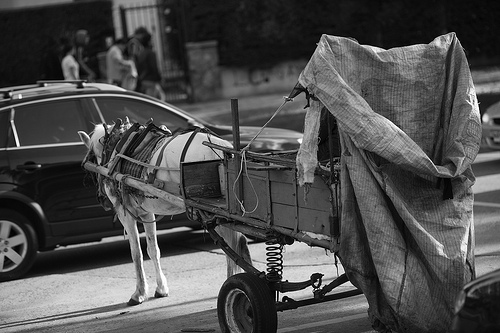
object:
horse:
[75, 121, 235, 306]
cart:
[84, 80, 499, 333]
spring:
[261, 223, 282, 282]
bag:
[290, 33, 479, 331]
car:
[0, 77, 306, 280]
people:
[60, 44, 81, 80]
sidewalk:
[202, 79, 499, 128]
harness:
[104, 130, 178, 181]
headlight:
[481, 113, 491, 123]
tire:
[215, 271, 279, 333]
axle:
[277, 286, 361, 310]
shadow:
[0, 289, 500, 333]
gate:
[105, 0, 185, 77]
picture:
[0, 0, 500, 333]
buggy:
[234, 145, 424, 240]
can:
[181, 39, 221, 101]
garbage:
[185, 40, 223, 100]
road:
[0, 71, 497, 333]